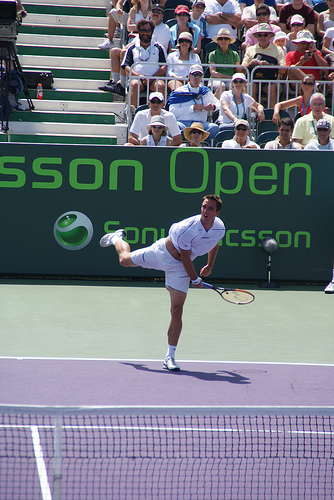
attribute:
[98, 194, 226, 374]
player — male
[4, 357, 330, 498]
court — purple, grey, lavender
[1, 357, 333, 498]
lines — white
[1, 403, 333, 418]
tape — white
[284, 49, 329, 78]
shirt — red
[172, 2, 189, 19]
hat — red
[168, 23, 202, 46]
sweater — blue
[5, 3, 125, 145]
steps — green, white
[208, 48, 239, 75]
shirt — green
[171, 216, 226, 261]
shirt — white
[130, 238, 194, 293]
pants — white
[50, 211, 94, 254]
logo — sony ericsson, green, lavender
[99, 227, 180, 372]
tennis shoes — white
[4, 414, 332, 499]
mesh — square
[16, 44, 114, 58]
riser — green